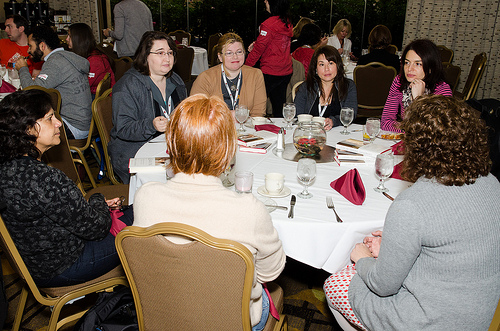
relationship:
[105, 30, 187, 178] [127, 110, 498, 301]
woman in table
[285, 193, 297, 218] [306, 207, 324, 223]
knife on table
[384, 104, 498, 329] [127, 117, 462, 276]
woman sitting at table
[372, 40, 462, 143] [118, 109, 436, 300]
woman sitting at table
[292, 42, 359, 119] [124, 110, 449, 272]
woman sitting at dinner table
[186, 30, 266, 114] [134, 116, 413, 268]
woman sitting at dinner table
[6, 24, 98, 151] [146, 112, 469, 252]
man sitting at dinner table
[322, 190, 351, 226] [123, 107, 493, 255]
fork sitting at table